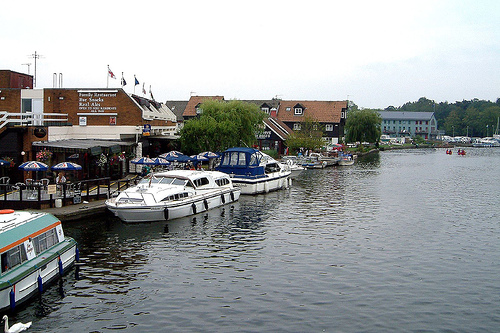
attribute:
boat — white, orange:
[106, 174, 233, 220]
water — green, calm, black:
[279, 255, 345, 304]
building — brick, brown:
[53, 95, 151, 126]